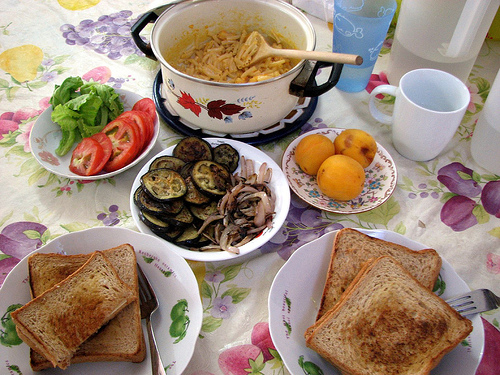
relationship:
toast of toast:
[305, 253, 473, 374] [305, 253, 473, 374]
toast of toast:
[12, 250, 137, 367] [12, 250, 137, 364]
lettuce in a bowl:
[52, 76, 123, 158] [30, 87, 161, 180]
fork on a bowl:
[445, 289, 500, 316] [268, 228, 486, 374]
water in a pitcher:
[387, 35, 478, 106] [387, 0, 500, 88]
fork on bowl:
[445, 289, 500, 316] [268, 228, 486, 374]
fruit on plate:
[317, 154, 365, 202] [283, 128, 399, 214]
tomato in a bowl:
[68, 98, 157, 177] [30, 87, 161, 180]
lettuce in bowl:
[52, 76, 123, 158] [30, 87, 161, 180]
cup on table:
[368, 68, 471, 161] [1, 1, 498, 374]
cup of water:
[332, 1, 396, 92] [335, 65, 375, 94]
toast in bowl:
[305, 253, 473, 374] [268, 228, 486, 374]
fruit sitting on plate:
[317, 154, 365, 202] [283, 128, 399, 214]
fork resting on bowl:
[445, 289, 500, 316] [268, 228, 486, 374]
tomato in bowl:
[68, 98, 157, 177] [30, 87, 161, 180]